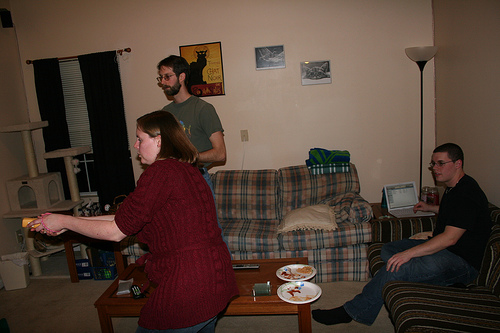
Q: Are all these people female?
A: No, they are both male and female.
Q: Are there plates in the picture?
A: Yes, there is a plate.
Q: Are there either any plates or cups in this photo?
A: Yes, there is a plate.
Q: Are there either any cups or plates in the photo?
A: Yes, there is a plate.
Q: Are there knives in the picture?
A: No, there are no knives.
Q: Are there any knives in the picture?
A: No, there are no knives.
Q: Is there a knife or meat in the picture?
A: No, there are no knives or meat.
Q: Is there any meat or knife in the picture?
A: No, there are no knives or meat.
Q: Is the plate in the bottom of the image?
A: Yes, the plate is in the bottom of the image.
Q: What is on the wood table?
A: The plate is on the table.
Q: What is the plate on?
A: The plate is on the table.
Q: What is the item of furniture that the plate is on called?
A: The piece of furniture is a table.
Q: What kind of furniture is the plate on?
A: The plate is on the table.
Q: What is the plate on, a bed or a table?
A: The plate is on a table.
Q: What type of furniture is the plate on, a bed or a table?
A: The plate is on a table.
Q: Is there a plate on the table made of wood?
A: Yes, there is a plate on the table.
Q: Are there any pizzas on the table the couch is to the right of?
A: No, there is a plate on the table.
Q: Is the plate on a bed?
A: No, the plate is on the table.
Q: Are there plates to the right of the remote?
A: Yes, there is a plate to the right of the remote.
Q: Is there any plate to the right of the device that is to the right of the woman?
A: Yes, there is a plate to the right of the remote.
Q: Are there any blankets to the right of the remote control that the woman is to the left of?
A: No, there is a plate to the right of the remote.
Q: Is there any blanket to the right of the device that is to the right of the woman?
A: No, there is a plate to the right of the remote.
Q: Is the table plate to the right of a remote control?
A: Yes, the plate is to the right of a remote control.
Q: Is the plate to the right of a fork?
A: No, the plate is to the right of a remote control.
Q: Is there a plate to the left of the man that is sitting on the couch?
A: Yes, there is a plate to the left of the man.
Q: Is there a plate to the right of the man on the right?
A: No, the plate is to the left of the man.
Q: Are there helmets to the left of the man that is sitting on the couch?
A: No, there is a plate to the left of the man.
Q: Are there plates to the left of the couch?
A: Yes, there is a plate to the left of the couch.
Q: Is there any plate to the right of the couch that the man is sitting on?
A: No, the plate is to the left of the couch.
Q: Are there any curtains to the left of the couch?
A: No, there is a plate to the left of the couch.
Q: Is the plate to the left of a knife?
A: No, the plate is to the left of the couch.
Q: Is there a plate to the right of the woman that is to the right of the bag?
A: Yes, there is a plate to the right of the woman.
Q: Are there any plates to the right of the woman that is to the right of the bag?
A: Yes, there is a plate to the right of the woman.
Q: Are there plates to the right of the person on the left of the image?
A: Yes, there is a plate to the right of the woman.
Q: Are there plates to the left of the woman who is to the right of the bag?
A: No, the plate is to the right of the woman.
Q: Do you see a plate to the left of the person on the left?
A: No, the plate is to the right of the woman.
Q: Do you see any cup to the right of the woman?
A: No, there is a plate to the right of the woman.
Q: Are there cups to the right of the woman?
A: No, there is a plate to the right of the woman.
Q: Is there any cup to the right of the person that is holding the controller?
A: No, there is a plate to the right of the woman.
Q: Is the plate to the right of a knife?
A: No, the plate is to the right of a woman.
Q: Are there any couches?
A: Yes, there is a couch.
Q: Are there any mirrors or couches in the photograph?
A: Yes, there is a couch.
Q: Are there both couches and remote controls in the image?
A: Yes, there are both a couch and a remote control.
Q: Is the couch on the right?
A: Yes, the couch is on the right of the image.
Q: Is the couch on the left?
A: No, the couch is on the right of the image.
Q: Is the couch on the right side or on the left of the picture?
A: The couch is on the right of the image.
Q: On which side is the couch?
A: The couch is on the right of the image.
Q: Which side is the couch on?
A: The couch is on the right of the image.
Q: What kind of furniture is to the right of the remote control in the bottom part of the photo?
A: The piece of furniture is a couch.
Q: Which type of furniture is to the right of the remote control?
A: The piece of furniture is a couch.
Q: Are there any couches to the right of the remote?
A: Yes, there is a couch to the right of the remote.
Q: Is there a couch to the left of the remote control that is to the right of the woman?
A: No, the couch is to the right of the remote.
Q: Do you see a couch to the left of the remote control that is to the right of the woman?
A: No, the couch is to the right of the remote.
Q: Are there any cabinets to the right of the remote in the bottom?
A: No, there is a couch to the right of the remote control.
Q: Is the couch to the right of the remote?
A: Yes, the couch is to the right of the remote.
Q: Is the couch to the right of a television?
A: No, the couch is to the right of the remote.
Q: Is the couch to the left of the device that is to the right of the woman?
A: No, the couch is to the right of the remote.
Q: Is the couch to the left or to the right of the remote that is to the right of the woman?
A: The couch is to the right of the remote.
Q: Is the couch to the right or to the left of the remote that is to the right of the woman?
A: The couch is to the right of the remote.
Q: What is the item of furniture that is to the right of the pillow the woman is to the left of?
A: The piece of furniture is a couch.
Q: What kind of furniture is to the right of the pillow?
A: The piece of furniture is a couch.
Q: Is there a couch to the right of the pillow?
A: Yes, there is a couch to the right of the pillow.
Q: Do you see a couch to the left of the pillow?
A: No, the couch is to the right of the pillow.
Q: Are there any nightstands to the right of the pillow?
A: No, there is a couch to the right of the pillow.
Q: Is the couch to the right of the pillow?
A: Yes, the couch is to the right of the pillow.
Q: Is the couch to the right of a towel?
A: No, the couch is to the right of the pillow.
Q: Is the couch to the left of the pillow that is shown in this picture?
A: No, the couch is to the right of the pillow.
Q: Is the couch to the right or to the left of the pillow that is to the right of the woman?
A: The couch is to the right of the pillow.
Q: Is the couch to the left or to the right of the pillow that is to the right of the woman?
A: The couch is to the right of the pillow.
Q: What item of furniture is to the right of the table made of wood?
A: The piece of furniture is a couch.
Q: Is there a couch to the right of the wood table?
A: Yes, there is a couch to the right of the table.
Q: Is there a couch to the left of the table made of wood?
A: No, the couch is to the right of the table.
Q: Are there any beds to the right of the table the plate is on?
A: No, there is a couch to the right of the table.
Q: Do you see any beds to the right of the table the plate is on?
A: No, there is a couch to the right of the table.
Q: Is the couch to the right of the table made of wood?
A: Yes, the couch is to the right of the table.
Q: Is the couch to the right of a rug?
A: No, the couch is to the right of the table.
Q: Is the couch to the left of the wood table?
A: No, the couch is to the right of the table.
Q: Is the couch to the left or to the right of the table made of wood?
A: The couch is to the right of the table.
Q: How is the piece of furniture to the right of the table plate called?
A: The piece of furniture is a couch.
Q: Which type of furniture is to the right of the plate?
A: The piece of furniture is a couch.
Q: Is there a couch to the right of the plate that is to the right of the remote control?
A: Yes, there is a couch to the right of the plate.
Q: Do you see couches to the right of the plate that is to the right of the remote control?
A: Yes, there is a couch to the right of the plate.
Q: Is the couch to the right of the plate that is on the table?
A: Yes, the couch is to the right of the plate.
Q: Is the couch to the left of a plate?
A: No, the couch is to the right of a plate.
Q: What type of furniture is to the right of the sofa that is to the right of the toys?
A: The piece of furniture is a couch.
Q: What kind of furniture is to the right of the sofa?
A: The piece of furniture is a couch.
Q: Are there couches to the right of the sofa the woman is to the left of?
A: Yes, there is a couch to the right of the sofa.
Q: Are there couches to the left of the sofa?
A: No, the couch is to the right of the sofa.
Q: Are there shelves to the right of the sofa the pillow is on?
A: No, there is a couch to the right of the sofa.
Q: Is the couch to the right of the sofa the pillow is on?
A: Yes, the couch is to the right of the sofa.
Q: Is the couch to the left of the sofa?
A: No, the couch is to the right of the sofa.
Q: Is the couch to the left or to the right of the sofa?
A: The couch is to the right of the sofa.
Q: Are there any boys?
A: No, there are no boys.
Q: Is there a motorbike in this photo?
A: No, there are no motorcycles.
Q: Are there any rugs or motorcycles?
A: No, there are no motorcycles or rugs.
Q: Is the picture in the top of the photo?
A: Yes, the picture is in the top of the image.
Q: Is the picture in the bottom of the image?
A: No, the picture is in the top of the image.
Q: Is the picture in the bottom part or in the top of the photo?
A: The picture is in the top of the image.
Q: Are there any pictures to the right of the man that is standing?
A: Yes, there is a picture to the right of the man.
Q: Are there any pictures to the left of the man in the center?
A: No, the picture is to the right of the man.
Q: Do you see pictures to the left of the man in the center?
A: No, the picture is to the right of the man.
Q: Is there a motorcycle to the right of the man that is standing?
A: No, there is a picture to the right of the man.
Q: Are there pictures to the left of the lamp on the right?
A: Yes, there is a picture to the left of the lamp.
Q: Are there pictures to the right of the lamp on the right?
A: No, the picture is to the left of the lamp.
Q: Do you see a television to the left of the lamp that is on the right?
A: No, there is a picture to the left of the lamp.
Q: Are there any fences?
A: No, there are no fences.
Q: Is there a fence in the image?
A: No, there are no fences.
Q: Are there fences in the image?
A: No, there are no fences.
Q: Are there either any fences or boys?
A: No, there are no fences or boys.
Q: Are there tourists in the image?
A: No, there are no tourists.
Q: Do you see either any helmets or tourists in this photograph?
A: No, there are no tourists or helmets.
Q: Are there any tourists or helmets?
A: No, there are no tourists or helmets.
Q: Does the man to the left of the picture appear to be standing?
A: Yes, the man is standing.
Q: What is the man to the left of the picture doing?
A: The man is standing.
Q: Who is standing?
A: The man is standing.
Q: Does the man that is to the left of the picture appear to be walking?
A: No, the man is standing.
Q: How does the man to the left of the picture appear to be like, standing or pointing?
A: The man is standing.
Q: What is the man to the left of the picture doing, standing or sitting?
A: The man is standing.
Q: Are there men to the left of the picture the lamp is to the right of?
A: Yes, there is a man to the left of the picture.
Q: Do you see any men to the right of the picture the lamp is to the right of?
A: No, the man is to the left of the picture.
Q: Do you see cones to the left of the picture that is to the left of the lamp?
A: No, there is a man to the left of the picture.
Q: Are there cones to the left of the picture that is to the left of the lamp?
A: No, there is a man to the left of the picture.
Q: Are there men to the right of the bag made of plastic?
A: Yes, there are men to the right of the bag.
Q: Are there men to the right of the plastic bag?
A: Yes, there are men to the right of the bag.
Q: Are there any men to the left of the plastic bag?
A: No, the men are to the right of the bag.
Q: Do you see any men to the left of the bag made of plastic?
A: No, the men are to the right of the bag.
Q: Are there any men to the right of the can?
A: Yes, there are men to the right of the can.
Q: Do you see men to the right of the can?
A: Yes, there are men to the right of the can.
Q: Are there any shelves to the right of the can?
A: No, there are men to the right of the can.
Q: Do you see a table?
A: Yes, there is a table.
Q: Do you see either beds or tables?
A: Yes, there is a table.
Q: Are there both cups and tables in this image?
A: No, there is a table but no cups.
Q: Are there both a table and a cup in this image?
A: No, there is a table but no cups.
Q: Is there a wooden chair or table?
A: Yes, there is a wood table.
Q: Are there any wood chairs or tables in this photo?
A: Yes, there is a wood table.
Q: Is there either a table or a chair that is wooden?
A: Yes, the table is wooden.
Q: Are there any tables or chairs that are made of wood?
A: Yes, the table is made of wood.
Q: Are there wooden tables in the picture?
A: Yes, there is a wood table.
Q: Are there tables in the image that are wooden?
A: Yes, there is a table that is wooden.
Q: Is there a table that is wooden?
A: Yes, there is a table that is wooden.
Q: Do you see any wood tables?
A: Yes, there is a table that is made of wood.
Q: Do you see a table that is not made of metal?
A: Yes, there is a table that is made of wood.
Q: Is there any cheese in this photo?
A: No, there is no cheese.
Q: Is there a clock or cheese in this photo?
A: No, there are no cheese or clocks.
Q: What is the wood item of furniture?
A: The piece of furniture is a table.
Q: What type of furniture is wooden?
A: The furniture is a table.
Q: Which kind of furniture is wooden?
A: The furniture is a table.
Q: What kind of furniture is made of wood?
A: The furniture is a table.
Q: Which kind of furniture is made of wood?
A: The furniture is a table.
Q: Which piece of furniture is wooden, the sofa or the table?
A: The table is wooden.